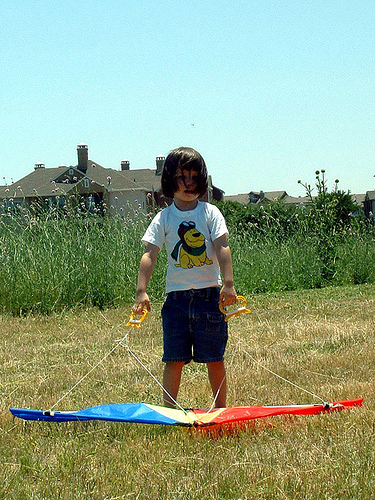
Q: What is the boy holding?
A: A kite.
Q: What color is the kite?
A: Blue, red and yellow.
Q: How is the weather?
A: Sunny.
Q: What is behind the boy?
A: Tall grass and a house.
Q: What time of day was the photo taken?
A: Daytime.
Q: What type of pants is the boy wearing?
A: Jeans.